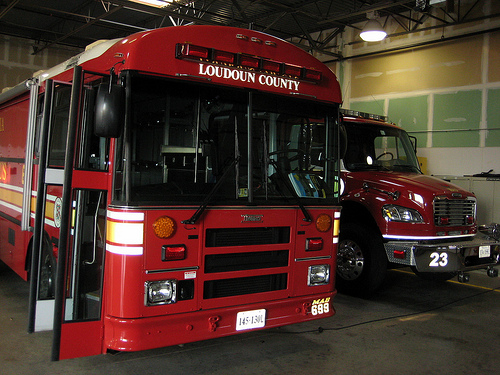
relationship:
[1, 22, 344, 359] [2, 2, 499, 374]
truck in shed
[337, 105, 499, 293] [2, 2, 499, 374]
truck in shed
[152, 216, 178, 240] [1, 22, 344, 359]
light on truck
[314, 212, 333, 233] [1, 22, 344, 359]
light on truck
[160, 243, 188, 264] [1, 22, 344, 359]
light on truck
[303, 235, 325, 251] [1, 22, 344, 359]
light on truck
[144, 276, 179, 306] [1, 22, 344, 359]
light on truck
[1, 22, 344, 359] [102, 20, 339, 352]
truck has front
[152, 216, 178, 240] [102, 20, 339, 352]
light on front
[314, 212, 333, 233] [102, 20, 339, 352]
light on front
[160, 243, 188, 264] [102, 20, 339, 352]
light on front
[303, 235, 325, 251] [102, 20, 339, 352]
light on front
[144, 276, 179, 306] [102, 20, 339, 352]
light on front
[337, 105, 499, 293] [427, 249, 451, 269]
truck has number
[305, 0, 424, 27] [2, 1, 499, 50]
rod in ceiling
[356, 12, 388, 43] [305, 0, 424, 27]
light on rod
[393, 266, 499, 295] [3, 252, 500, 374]
line on floor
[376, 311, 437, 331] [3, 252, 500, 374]
line on floor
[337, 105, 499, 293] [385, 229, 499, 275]
truck has bumper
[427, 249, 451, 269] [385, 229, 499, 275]
number on bumper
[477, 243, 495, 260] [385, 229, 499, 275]
license plate on bumper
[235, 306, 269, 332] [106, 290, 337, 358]
license plate on bumper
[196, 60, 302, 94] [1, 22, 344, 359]
letters on truck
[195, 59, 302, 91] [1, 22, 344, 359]
louden county on truck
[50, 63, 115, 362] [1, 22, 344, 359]
door on truck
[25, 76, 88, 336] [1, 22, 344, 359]
door on truck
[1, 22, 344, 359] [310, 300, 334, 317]
truck has number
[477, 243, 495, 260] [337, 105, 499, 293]
license plate on truck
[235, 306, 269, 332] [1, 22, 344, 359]
license plate on truck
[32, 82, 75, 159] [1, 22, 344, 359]
window on truck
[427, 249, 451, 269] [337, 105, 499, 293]
number on truck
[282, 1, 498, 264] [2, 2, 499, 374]
wall in shed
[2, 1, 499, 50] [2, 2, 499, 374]
ceiling in shed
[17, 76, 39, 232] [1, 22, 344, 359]
guard on truck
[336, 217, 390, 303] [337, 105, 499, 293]
wheel on truck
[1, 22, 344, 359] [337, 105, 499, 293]
truck next to truck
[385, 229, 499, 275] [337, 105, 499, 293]
bumper on truck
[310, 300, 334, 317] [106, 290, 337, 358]
number on bumper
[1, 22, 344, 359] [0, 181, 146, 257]
truck has stripes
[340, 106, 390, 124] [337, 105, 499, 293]
light on truck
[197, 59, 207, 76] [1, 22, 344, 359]
letter on truck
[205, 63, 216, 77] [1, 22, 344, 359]
letter on truck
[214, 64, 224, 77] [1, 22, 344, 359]
letter on truck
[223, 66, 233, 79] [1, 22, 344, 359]
letter on truck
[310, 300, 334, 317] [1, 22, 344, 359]
number on truck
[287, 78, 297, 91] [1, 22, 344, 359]
letter on truck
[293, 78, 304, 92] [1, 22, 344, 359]
letter on truck